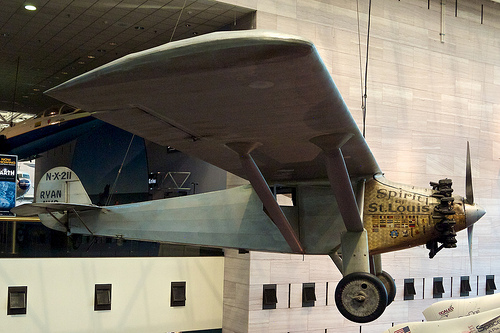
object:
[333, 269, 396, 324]
two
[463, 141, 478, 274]
propeller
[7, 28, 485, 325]
airplane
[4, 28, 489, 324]
hanging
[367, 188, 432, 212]
spirit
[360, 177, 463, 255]
decal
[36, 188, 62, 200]
ryan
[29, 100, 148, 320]
tail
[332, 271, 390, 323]
tires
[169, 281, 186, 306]
windows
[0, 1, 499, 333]
building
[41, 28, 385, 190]
wing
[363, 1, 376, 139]
cable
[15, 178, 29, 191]
nose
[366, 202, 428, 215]
writing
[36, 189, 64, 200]
writing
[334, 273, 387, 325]
wheels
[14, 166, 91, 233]
fin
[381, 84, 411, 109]
tiles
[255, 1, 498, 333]
wall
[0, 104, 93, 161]
plane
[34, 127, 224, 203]
wall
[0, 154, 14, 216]
sign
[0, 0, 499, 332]
museum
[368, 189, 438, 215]
name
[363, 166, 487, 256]
nose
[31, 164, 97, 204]
tail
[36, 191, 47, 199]
letters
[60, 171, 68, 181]
numbers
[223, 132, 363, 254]
braces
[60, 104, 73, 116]
cockpit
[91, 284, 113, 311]
squares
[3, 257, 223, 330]
wall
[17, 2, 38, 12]
light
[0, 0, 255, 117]
ceiling